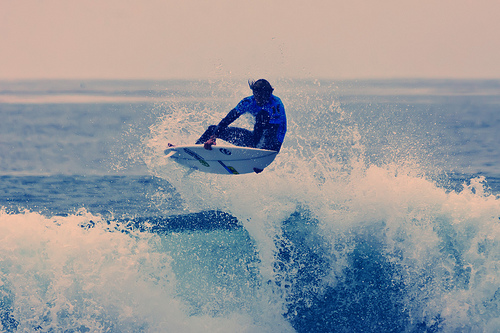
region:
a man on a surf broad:
[141, 61, 331, 198]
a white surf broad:
[165, 142, 277, 182]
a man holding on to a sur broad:
[201, 80, 296, 149]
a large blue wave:
[28, 175, 468, 303]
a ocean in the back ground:
[22, 80, 154, 140]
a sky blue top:
[242, 95, 299, 132]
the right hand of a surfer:
[201, 139, 223, 150]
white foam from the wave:
[32, 229, 147, 306]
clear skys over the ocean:
[46, 12, 481, 68]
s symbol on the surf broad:
[201, 146, 241, 161]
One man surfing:
[160, 80, 314, 190]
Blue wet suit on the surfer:
[184, 87, 309, 172]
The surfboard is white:
[127, 135, 297, 182]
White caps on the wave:
[22, 153, 493, 307]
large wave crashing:
[2, 146, 487, 322]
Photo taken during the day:
[9, 10, 491, 322]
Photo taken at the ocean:
[0, 21, 488, 323]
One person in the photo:
[140, 45, 347, 201]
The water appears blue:
[6, 72, 491, 326]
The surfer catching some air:
[134, 65, 338, 220]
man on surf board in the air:
[161, 80, 288, 179]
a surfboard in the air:
[162, 143, 277, 181]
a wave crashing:
[3, 172, 496, 332]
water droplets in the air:
[299, 81, 373, 178]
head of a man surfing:
[248, 76, 275, 105]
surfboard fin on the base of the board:
[161, 150, 179, 160]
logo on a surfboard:
[220, 146, 232, 156]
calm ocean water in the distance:
[4, 77, 150, 173]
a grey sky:
[0, 1, 499, 77]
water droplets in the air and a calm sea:
[355, 78, 495, 178]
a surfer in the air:
[151, 72, 308, 188]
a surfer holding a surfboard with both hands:
[151, 69, 298, 192]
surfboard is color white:
[147, 139, 280, 186]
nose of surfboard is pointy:
[245, 141, 283, 175]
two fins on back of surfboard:
[151, 148, 203, 186]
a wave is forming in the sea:
[0, 69, 499, 331]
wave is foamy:
[6, 207, 258, 329]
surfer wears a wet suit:
[190, 73, 291, 183]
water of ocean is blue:
[6, 70, 499, 331]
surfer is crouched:
[176, 67, 301, 192]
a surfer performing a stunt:
[129, 55, 324, 201]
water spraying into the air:
[325, 105, 392, 170]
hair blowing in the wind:
[251, 75, 257, 87]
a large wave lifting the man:
[37, 203, 313, 302]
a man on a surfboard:
[161, 52, 328, 232]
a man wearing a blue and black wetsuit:
[196, 71, 291, 155]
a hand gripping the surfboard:
[204, 137, 213, 149]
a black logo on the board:
[215, 144, 232, 158]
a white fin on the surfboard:
[163, 147, 180, 160]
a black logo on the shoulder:
[271, 100, 286, 115]